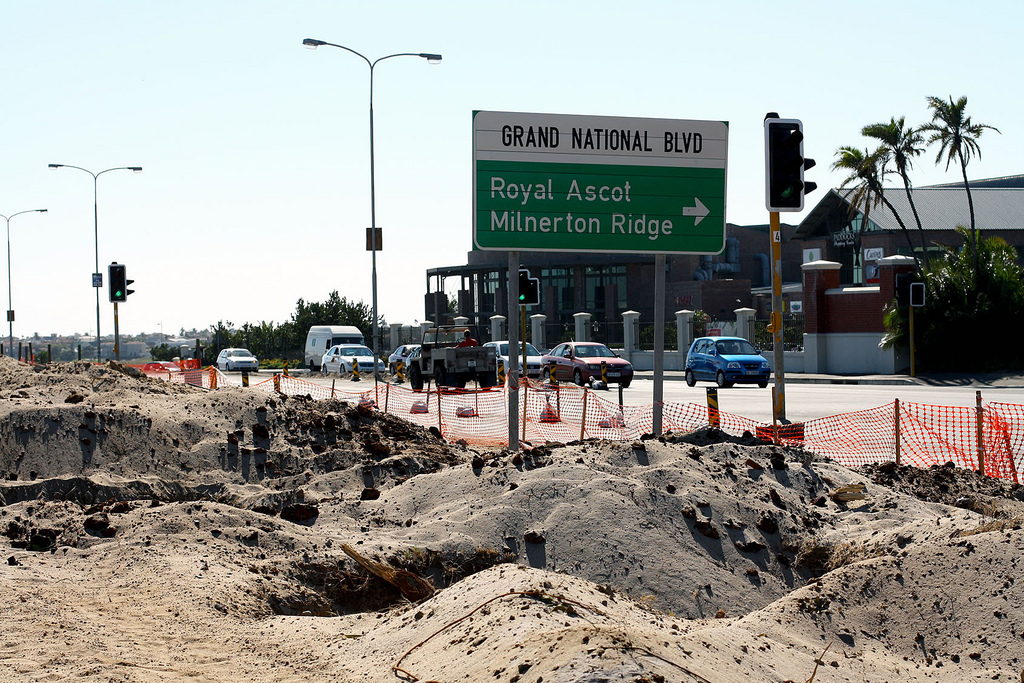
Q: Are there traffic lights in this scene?
A: Yes, there is a traffic light.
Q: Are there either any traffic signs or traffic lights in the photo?
A: Yes, there is a traffic light.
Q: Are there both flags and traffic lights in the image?
A: No, there is a traffic light but no flags.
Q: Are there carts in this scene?
A: No, there are no carts.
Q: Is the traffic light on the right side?
A: Yes, the traffic light is on the right of the image.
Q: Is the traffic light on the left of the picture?
A: No, the traffic light is on the right of the image.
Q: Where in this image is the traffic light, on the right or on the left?
A: The traffic light is on the right of the image.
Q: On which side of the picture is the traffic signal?
A: The traffic signal is on the right of the image.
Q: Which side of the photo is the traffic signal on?
A: The traffic signal is on the right of the image.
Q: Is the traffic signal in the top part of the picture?
A: Yes, the traffic signal is in the top of the image.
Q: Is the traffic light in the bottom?
A: No, the traffic light is in the top of the image.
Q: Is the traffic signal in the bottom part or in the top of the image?
A: The traffic signal is in the top of the image.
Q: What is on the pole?
A: The traffic light is on the pole.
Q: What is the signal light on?
A: The signal light is on the pole.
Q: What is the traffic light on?
A: The signal light is on the pole.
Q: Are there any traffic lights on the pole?
A: Yes, there is a traffic light on the pole.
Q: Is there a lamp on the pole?
A: No, there is a traffic light on the pole.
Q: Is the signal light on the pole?
A: Yes, the signal light is on the pole.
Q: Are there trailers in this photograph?
A: No, there are no trailers.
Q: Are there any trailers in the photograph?
A: No, there are no trailers.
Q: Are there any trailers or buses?
A: No, there are no trailers or buses.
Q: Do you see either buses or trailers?
A: No, there are no trailers or buses.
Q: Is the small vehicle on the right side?
A: Yes, the car is on the right of the image.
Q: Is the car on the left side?
A: No, the car is on the right of the image.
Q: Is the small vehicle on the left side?
A: No, the car is on the right of the image.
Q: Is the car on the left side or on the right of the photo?
A: The car is on the right of the image.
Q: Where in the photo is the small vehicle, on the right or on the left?
A: The car is on the right of the image.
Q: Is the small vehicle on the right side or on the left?
A: The car is on the right of the image.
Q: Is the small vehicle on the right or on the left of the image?
A: The car is on the right of the image.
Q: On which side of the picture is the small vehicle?
A: The car is on the right of the image.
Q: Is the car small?
A: Yes, the car is small.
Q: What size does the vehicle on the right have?
A: The car has small size.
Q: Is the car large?
A: No, the car is small.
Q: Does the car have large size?
A: No, the car is small.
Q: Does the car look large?
A: No, the car is small.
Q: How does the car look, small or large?
A: The car is small.